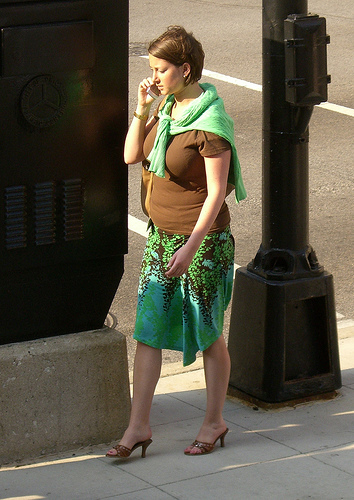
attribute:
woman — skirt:
[103, 25, 236, 463]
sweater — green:
[148, 93, 254, 204]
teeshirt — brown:
[128, 115, 207, 251]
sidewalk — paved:
[28, 434, 165, 494]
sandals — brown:
[98, 428, 240, 468]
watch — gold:
[128, 110, 151, 126]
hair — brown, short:
[147, 30, 207, 101]